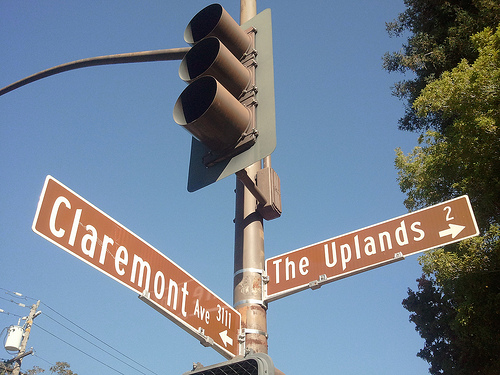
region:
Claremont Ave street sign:
[20, 158, 246, 364]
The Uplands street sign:
[257, 173, 478, 306]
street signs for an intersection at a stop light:
[25, 156, 477, 332]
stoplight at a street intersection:
[172, 0, 289, 183]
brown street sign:
[30, 170, 252, 358]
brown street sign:
[247, 183, 476, 296]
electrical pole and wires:
[1, 279, 89, 374]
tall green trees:
[402, 1, 494, 360]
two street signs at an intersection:
[40, 168, 489, 333]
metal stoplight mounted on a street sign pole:
[175, 6, 297, 374]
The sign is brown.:
[32, 159, 482, 330]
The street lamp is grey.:
[161, 1, 298, 190]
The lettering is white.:
[257, 226, 469, 288]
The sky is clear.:
[286, 21, 403, 210]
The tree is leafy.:
[402, 17, 478, 239]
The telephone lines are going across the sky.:
[10, 294, 126, 374]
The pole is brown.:
[235, 178, 301, 372]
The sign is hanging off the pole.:
[222, 212, 497, 322]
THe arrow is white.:
[427, 214, 475, 242]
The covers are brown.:
[183, 1, 250, 174]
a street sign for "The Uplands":
[270, 185, 479, 304]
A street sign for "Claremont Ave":
[45, 178, 246, 365]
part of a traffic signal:
[173, 75, 250, 156]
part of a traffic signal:
[176, 37, 252, 91]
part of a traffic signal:
[179, 2, 251, 57]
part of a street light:
[4, 39, 228, 102]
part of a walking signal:
[179, 353, 282, 373]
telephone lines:
[4, 283, 152, 373]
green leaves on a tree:
[391, 0, 499, 93]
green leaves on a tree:
[429, 255, 499, 372]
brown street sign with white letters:
[25, 173, 245, 363]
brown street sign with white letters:
[257, 193, 486, 304]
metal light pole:
[227, 0, 277, 374]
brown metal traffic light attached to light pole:
[168, 1, 280, 196]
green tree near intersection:
[379, 1, 498, 373]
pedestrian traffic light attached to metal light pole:
[158, 350, 309, 374]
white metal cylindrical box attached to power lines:
[2, 317, 27, 355]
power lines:
[0, 284, 170, 374]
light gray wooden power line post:
[3, 291, 46, 373]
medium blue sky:
[0, 0, 450, 374]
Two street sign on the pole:
[27, 157, 492, 319]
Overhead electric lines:
[2, 278, 139, 373]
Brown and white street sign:
[28, 170, 262, 344]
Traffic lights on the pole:
[154, 0, 267, 165]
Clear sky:
[30, 30, 156, 185]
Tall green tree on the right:
[370, 0, 492, 370]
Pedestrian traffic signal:
[185, 352, 275, 372]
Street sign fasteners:
[230, 256, 276, 343]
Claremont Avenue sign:
[30, 175, 245, 346]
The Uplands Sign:
[248, 190, 494, 296]